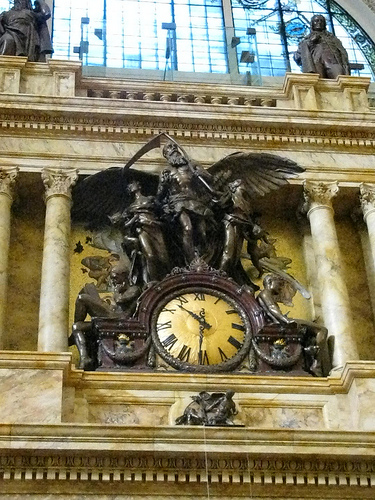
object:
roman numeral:
[217, 346, 227, 362]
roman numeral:
[176, 344, 191, 362]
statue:
[119, 180, 171, 286]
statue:
[219, 178, 271, 280]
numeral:
[193, 292, 206, 301]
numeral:
[198, 349, 210, 365]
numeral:
[161, 333, 178, 351]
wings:
[70, 150, 307, 221]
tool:
[123, 130, 215, 194]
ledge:
[0, 351, 375, 399]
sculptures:
[67, 132, 332, 379]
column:
[36, 167, 80, 354]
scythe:
[121, 129, 215, 193]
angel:
[71, 130, 306, 270]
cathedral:
[0, 0, 375, 500]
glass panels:
[52, 0, 375, 77]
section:
[200, 288, 253, 371]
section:
[148, 285, 200, 369]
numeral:
[214, 297, 222, 305]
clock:
[149, 286, 252, 375]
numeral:
[225, 308, 239, 315]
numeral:
[232, 323, 245, 332]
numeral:
[227, 335, 242, 351]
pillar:
[36, 157, 78, 354]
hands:
[176, 302, 212, 364]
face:
[155, 292, 246, 366]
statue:
[174, 388, 239, 426]